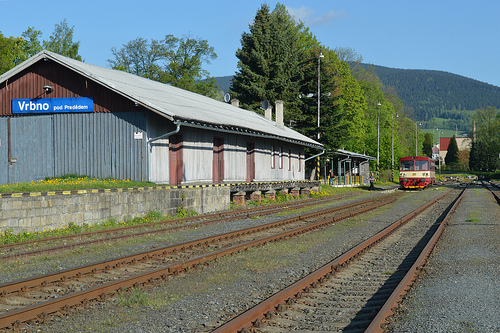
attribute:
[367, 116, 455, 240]
train — red , white 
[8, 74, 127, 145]
sign — blue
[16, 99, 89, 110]
writing — white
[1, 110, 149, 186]
siding — gray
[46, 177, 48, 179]
flower — yellow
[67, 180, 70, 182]
flower — yellow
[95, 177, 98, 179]
flower — yellow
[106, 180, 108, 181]
flower — yellow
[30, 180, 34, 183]
flower — yellow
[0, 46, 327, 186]
barn — big, large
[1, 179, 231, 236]
wall — stone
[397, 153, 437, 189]
train car — red, white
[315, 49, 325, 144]
security light — tall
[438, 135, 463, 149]
roof — red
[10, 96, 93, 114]
sign — blue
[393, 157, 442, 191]
train — red, white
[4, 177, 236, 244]
wall — short, stone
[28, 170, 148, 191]
flowers — yellow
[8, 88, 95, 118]
sign — blue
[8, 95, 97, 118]
sign — blue, white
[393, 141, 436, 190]
train — red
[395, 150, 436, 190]
train — red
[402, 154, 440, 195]
train — red